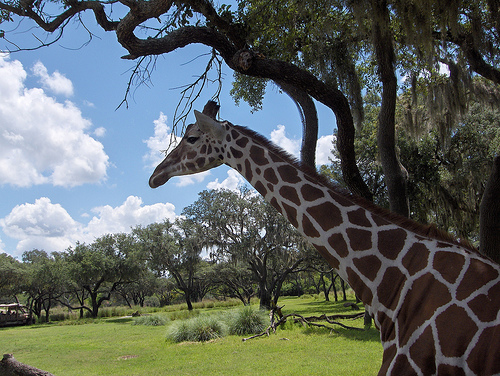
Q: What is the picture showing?
A: It is showing a field.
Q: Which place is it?
A: It is a field.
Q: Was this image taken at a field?
A: Yes, it was taken in a field.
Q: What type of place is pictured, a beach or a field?
A: It is a field.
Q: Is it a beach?
A: No, it is a field.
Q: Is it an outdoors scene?
A: Yes, it is outdoors.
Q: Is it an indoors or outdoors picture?
A: It is outdoors.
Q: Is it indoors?
A: No, it is outdoors.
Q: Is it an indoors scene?
A: No, it is outdoors.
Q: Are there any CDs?
A: No, there are no cds.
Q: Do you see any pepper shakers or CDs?
A: No, there are no CDs or pepper shakers.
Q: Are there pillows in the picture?
A: No, there are no pillows.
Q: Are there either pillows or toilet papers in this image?
A: No, there are no pillows or toilet papers.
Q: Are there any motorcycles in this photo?
A: No, there are no motorcycles.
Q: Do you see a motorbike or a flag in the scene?
A: No, there are no motorcycles or flags.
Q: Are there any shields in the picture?
A: No, there are no shields.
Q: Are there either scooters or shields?
A: No, there are no shields or scooters.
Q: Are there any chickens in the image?
A: No, there are no chickens.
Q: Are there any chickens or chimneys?
A: No, there are no chickens or chimneys.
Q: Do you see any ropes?
A: No, there are no ropes.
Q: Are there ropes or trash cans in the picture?
A: No, there are no ropes or trash cans.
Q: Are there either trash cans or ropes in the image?
A: No, there are no ropes or trash cans.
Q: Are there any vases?
A: No, there are no vases.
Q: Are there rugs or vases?
A: No, there are no vases or rugs.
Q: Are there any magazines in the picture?
A: No, there are no magazines.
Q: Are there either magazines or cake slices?
A: No, there are no magazines or cake slices.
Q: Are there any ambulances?
A: No, there are no ambulances.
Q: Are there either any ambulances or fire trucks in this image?
A: No, there are no ambulances or fire trucks.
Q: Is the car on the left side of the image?
A: Yes, the car is on the left of the image.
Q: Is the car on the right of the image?
A: No, the car is on the left of the image.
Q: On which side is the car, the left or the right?
A: The car is on the left of the image.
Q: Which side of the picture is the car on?
A: The car is on the left of the image.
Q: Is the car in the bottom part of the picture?
A: Yes, the car is in the bottom of the image.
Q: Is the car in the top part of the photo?
A: No, the car is in the bottom of the image.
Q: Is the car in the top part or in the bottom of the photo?
A: The car is in the bottom of the image.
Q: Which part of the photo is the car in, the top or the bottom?
A: The car is in the bottom of the image.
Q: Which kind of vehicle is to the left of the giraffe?
A: The vehicle is a car.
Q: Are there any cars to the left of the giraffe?
A: Yes, there is a car to the left of the giraffe.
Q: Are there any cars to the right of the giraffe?
A: No, the car is to the left of the giraffe.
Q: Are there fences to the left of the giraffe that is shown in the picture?
A: No, there is a car to the left of the giraffe.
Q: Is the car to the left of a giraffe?
A: Yes, the car is to the left of a giraffe.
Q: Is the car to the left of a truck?
A: No, the car is to the left of a giraffe.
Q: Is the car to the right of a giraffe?
A: No, the car is to the left of a giraffe.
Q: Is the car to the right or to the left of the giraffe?
A: The car is to the left of the giraffe.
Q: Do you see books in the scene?
A: No, there are no books.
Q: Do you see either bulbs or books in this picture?
A: No, there are no books or bulbs.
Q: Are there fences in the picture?
A: No, there are no fences.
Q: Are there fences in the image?
A: No, there are no fences.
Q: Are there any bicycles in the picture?
A: No, there are no bicycles.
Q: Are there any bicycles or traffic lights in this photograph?
A: No, there are no bicycles or traffic lights.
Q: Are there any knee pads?
A: No, there are no knee pads.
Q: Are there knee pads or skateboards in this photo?
A: No, there are no knee pads or skateboards.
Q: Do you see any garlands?
A: No, there are no garlands.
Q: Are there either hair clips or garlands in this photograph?
A: No, there are no garlands or hair clips.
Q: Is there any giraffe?
A: Yes, there is a giraffe.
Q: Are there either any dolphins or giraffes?
A: Yes, there is a giraffe.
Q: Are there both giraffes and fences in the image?
A: No, there is a giraffe but no fences.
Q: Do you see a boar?
A: No, there are no boars.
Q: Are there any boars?
A: No, there are no boars.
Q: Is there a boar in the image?
A: No, there are no boars.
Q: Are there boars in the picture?
A: No, there are no boars.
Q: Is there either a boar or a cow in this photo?
A: No, there are no boars or cows.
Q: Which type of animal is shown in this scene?
A: The animal is a giraffe.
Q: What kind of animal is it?
A: The animal is a giraffe.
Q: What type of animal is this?
A: This is a giraffe.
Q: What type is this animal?
A: This is a giraffe.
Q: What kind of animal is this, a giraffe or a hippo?
A: This is a giraffe.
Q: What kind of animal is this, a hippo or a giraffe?
A: This is a giraffe.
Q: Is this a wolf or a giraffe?
A: This is a giraffe.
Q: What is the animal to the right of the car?
A: The animal is a giraffe.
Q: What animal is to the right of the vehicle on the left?
A: The animal is a giraffe.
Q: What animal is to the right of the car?
A: The animal is a giraffe.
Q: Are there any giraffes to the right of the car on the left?
A: Yes, there is a giraffe to the right of the car.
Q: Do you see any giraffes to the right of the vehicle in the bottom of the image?
A: Yes, there is a giraffe to the right of the car.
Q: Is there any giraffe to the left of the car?
A: No, the giraffe is to the right of the car.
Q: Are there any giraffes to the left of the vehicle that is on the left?
A: No, the giraffe is to the right of the car.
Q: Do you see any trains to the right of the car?
A: No, there is a giraffe to the right of the car.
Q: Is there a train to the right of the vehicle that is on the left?
A: No, there is a giraffe to the right of the car.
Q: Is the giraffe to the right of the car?
A: Yes, the giraffe is to the right of the car.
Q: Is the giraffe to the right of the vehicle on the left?
A: Yes, the giraffe is to the right of the car.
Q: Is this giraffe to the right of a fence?
A: No, the giraffe is to the right of the car.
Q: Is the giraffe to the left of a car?
A: No, the giraffe is to the right of a car.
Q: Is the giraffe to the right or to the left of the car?
A: The giraffe is to the right of the car.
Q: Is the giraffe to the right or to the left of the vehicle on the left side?
A: The giraffe is to the right of the car.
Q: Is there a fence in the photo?
A: No, there are no fences.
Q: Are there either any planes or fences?
A: No, there are no fences or planes.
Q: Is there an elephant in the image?
A: No, there are no elephants.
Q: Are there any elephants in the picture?
A: No, there are no elephants.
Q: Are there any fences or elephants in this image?
A: No, there are no elephants or fences.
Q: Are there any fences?
A: No, there are no fences.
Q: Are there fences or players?
A: No, there are no fences or players.